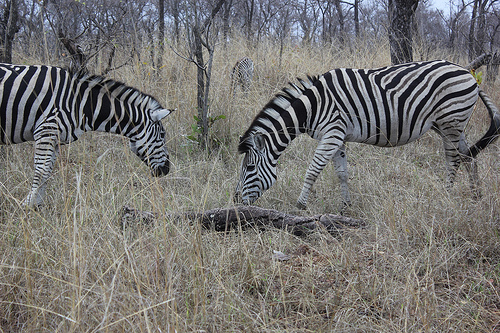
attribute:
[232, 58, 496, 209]
zebras — striped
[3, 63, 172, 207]
zebras — striped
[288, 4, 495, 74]
trees — bare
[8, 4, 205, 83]
trees — bare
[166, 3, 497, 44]
trees — leafless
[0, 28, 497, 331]
grass — long, dead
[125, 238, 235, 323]
grass — dry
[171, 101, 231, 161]
leaves — green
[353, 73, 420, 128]
stripes — black, white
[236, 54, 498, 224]
zebra — standing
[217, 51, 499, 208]
zebra — eating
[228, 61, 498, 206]
zebra — grazing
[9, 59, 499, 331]
grass — tall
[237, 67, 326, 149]
mane — black, white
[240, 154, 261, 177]
eye — black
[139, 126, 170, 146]
eye — black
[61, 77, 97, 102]
fur — grey, brownish